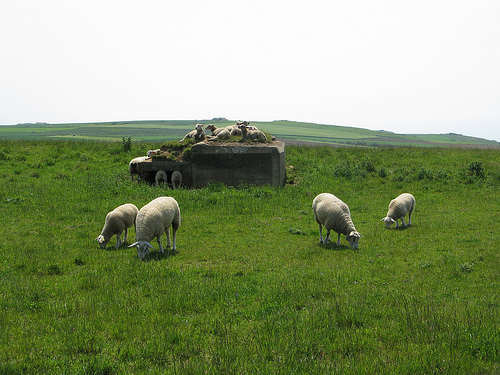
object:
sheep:
[311, 192, 364, 251]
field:
[0, 117, 499, 375]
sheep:
[381, 192, 417, 229]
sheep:
[179, 123, 205, 143]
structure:
[129, 127, 286, 190]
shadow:
[316, 239, 351, 250]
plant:
[122, 136, 133, 154]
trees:
[17, 122, 55, 127]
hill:
[0, 117, 495, 145]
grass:
[0, 120, 500, 375]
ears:
[349, 231, 355, 236]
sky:
[0, 0, 500, 143]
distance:
[90, 112, 139, 120]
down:
[349, 249, 354, 251]